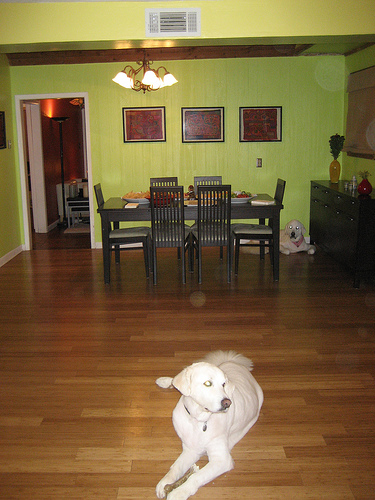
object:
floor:
[2, 249, 373, 498]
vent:
[144, 13, 201, 35]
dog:
[155, 349, 264, 499]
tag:
[203, 424, 209, 432]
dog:
[242, 221, 318, 257]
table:
[97, 196, 282, 284]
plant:
[329, 135, 345, 158]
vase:
[329, 159, 343, 184]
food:
[232, 190, 251, 202]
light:
[110, 55, 175, 97]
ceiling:
[4, 36, 370, 68]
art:
[120, 105, 166, 145]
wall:
[9, 55, 354, 248]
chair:
[92, 183, 150, 282]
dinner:
[124, 189, 254, 206]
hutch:
[308, 180, 372, 288]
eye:
[203, 380, 211, 390]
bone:
[162, 465, 202, 494]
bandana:
[295, 238, 307, 247]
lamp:
[52, 112, 69, 227]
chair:
[150, 177, 188, 260]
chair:
[151, 177, 188, 285]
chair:
[192, 176, 227, 255]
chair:
[231, 180, 288, 282]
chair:
[194, 186, 228, 281]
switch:
[255, 157, 263, 171]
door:
[17, 92, 96, 250]